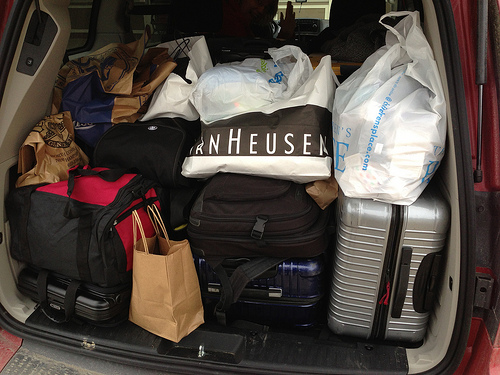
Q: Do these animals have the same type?
A: Yes, all the animals are cows.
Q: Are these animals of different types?
A: No, all the animals are cows.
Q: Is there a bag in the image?
A: Yes, there is a bag.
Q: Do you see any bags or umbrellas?
A: Yes, there is a bag.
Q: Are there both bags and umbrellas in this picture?
A: No, there is a bag but no umbrellas.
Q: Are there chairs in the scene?
A: No, there are no chairs.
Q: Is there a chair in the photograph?
A: No, there are no chairs.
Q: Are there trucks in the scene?
A: No, there are no trucks.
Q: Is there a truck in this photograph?
A: No, there are no trucks.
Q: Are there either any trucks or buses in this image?
A: No, there are no trucks or buses.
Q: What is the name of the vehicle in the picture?
A: The vehicle is a car.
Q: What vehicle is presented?
A: The vehicle is a car.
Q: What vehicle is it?
A: The vehicle is a car.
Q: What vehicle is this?
A: This is a car.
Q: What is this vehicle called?
A: This is a car.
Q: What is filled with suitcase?
A: The car is filled with suitcase.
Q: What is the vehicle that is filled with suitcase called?
A: The vehicle is a car.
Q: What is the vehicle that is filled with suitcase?
A: The vehicle is a car.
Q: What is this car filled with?
A: The car is filled with suitcase.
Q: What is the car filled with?
A: The car is filled with suitcase.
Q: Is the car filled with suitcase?
A: Yes, the car is filled with suitcase.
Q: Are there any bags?
A: Yes, there is a bag.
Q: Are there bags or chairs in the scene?
A: Yes, there is a bag.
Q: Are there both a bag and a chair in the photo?
A: No, there is a bag but no chairs.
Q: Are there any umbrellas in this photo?
A: No, there are no umbrellas.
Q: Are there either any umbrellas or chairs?
A: No, there are no umbrellas or chairs.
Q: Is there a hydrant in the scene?
A: No, there are no fire hydrants.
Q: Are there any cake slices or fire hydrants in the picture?
A: No, there are no fire hydrants or cake slices.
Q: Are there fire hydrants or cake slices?
A: No, there are no fire hydrants or cake slices.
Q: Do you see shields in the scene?
A: No, there are no shields.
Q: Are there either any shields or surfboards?
A: No, there are no shields or surfboards.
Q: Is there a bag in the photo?
A: Yes, there is a bag.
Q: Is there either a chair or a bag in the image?
A: Yes, there is a bag.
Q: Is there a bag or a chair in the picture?
A: Yes, there is a bag.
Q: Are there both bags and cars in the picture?
A: Yes, there are both a bag and a car.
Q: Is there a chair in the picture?
A: No, there are no chairs.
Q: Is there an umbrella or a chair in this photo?
A: No, there are no chairs or umbrellas.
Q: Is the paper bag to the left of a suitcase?
A: Yes, the bag is to the left of a suitcase.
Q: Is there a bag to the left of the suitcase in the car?
A: Yes, there is a bag to the left of the suitcase.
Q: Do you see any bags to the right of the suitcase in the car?
A: No, the bag is to the left of the suitcase.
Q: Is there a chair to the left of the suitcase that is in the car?
A: No, there is a bag to the left of the suitcase.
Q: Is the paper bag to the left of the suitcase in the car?
A: Yes, the bag is to the left of the suitcase.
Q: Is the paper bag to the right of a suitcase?
A: No, the bag is to the left of a suitcase.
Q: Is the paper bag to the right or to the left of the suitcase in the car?
A: The bag is to the left of the suitcase.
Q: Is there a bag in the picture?
A: Yes, there is a bag.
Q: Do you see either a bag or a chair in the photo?
A: Yes, there is a bag.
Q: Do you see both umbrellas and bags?
A: No, there is a bag but no umbrellas.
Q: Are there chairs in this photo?
A: No, there are no chairs.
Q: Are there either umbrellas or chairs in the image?
A: No, there are no chairs or umbrellas.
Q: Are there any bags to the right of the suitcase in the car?
A: No, the bag is to the left of the suitcase.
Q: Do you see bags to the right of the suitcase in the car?
A: No, the bag is to the left of the suitcase.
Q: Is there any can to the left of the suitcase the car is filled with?
A: No, there is a bag to the left of the suitcase.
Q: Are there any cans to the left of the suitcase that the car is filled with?
A: No, there is a bag to the left of the suitcase.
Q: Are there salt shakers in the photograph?
A: No, there are no salt shakers.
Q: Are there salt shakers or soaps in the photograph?
A: No, there are no salt shakers or soaps.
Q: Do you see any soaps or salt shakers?
A: No, there are no salt shakers or soaps.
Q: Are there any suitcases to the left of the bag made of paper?
A: No, the suitcase is to the right of the bag.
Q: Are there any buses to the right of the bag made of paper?
A: No, there is a suitcase to the right of the bag.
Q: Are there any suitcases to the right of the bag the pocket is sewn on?
A: Yes, there is a suitcase to the right of the bag.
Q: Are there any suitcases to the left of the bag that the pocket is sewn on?
A: No, the suitcase is to the right of the bag.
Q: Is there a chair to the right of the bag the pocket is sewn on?
A: No, there is a suitcase to the right of the bag.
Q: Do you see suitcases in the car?
A: Yes, there is a suitcase in the car.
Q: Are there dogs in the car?
A: No, there is a suitcase in the car.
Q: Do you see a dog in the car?
A: No, there is a suitcase in the car.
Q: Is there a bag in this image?
A: Yes, there is a bag.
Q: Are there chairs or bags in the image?
A: Yes, there is a bag.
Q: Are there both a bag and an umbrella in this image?
A: No, there is a bag but no umbrellas.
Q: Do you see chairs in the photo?
A: No, there are no chairs.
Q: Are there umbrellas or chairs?
A: No, there are no chairs or umbrellas.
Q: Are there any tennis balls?
A: No, there are no tennis balls.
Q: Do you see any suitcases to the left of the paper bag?
A: Yes, there are suitcases to the left of the bag.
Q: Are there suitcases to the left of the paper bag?
A: Yes, there are suitcases to the left of the bag.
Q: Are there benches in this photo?
A: No, there are no benches.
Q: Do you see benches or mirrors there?
A: No, there are no benches or mirrors.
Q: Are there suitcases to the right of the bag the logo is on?
A: Yes, there are suitcases to the right of the bag.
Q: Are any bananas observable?
A: No, there are no bananas.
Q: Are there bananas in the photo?
A: No, there are no bananas.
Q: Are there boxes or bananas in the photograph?
A: No, there are no bananas or boxes.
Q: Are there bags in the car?
A: Yes, there are bags in the car.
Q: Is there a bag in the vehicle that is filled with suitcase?
A: Yes, there are bags in the car.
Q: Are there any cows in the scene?
A: Yes, there are cows.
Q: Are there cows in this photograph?
A: Yes, there are cows.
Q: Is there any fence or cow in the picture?
A: Yes, there are cows.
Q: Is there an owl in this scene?
A: No, there are no owls.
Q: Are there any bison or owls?
A: No, there are no owls or bison.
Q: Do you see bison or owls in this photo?
A: No, there are no owls or bison.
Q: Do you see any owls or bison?
A: No, there are no owls or bison.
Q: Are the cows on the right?
A: Yes, the cows are on the right of the image.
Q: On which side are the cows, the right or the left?
A: The cows are on the right of the image.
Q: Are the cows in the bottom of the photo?
A: No, the cows are in the top of the image.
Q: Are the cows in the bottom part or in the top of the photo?
A: The cows are in the top of the image.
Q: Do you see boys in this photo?
A: No, there are no boys.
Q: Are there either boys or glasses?
A: No, there are no boys or glasses.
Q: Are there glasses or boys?
A: No, there are no boys or glasses.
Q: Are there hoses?
A: No, there are no hoses.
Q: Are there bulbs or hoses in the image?
A: No, there are no hoses or bulbs.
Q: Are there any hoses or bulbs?
A: No, there are no hoses or bulbs.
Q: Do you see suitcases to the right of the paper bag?
A: Yes, there is a suitcase to the right of the bag.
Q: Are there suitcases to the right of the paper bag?
A: Yes, there is a suitcase to the right of the bag.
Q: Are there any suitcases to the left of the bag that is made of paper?
A: No, the suitcase is to the right of the bag.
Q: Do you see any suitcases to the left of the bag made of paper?
A: No, the suitcase is to the right of the bag.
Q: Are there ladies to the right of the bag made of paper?
A: No, there is a suitcase to the right of the bag.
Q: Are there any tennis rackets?
A: No, there are no tennis rackets.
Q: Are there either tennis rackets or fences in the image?
A: No, there are no tennis rackets or fences.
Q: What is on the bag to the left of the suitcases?
A: The logo is on the bag.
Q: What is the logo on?
A: The logo is on the bag.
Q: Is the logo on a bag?
A: Yes, the logo is on a bag.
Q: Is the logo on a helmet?
A: No, the logo is on a bag.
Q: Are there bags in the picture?
A: Yes, there is a bag.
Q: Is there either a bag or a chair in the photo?
A: Yes, there is a bag.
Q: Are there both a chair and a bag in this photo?
A: No, there is a bag but no chairs.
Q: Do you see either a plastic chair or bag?
A: Yes, there is a plastic bag.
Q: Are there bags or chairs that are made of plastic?
A: Yes, the bag is made of plastic.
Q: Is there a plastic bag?
A: Yes, there is a bag that is made of plastic.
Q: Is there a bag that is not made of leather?
A: Yes, there is a bag that is made of plastic.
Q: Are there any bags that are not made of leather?
A: Yes, there is a bag that is made of plastic.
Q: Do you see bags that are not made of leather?
A: Yes, there is a bag that is made of plastic.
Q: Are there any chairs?
A: No, there are no chairs.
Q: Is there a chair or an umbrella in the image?
A: No, there are no chairs or umbrellas.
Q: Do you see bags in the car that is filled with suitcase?
A: Yes, there is a bag in the car.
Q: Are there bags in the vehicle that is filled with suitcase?
A: Yes, there is a bag in the car.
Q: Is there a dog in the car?
A: No, there is a bag in the car.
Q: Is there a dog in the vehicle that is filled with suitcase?
A: No, there is a bag in the car.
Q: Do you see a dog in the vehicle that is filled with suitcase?
A: No, there is a bag in the car.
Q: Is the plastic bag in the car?
A: Yes, the bag is in the car.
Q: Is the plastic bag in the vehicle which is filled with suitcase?
A: Yes, the bag is in the car.